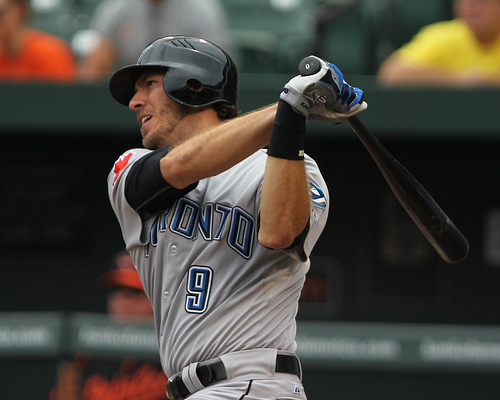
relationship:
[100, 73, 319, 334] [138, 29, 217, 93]
man in helmet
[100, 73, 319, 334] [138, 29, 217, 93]
man with helmet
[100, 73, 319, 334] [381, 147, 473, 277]
man swinging bat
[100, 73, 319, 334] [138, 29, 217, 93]
man wearing helmet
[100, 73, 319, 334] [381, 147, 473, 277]
man with bat